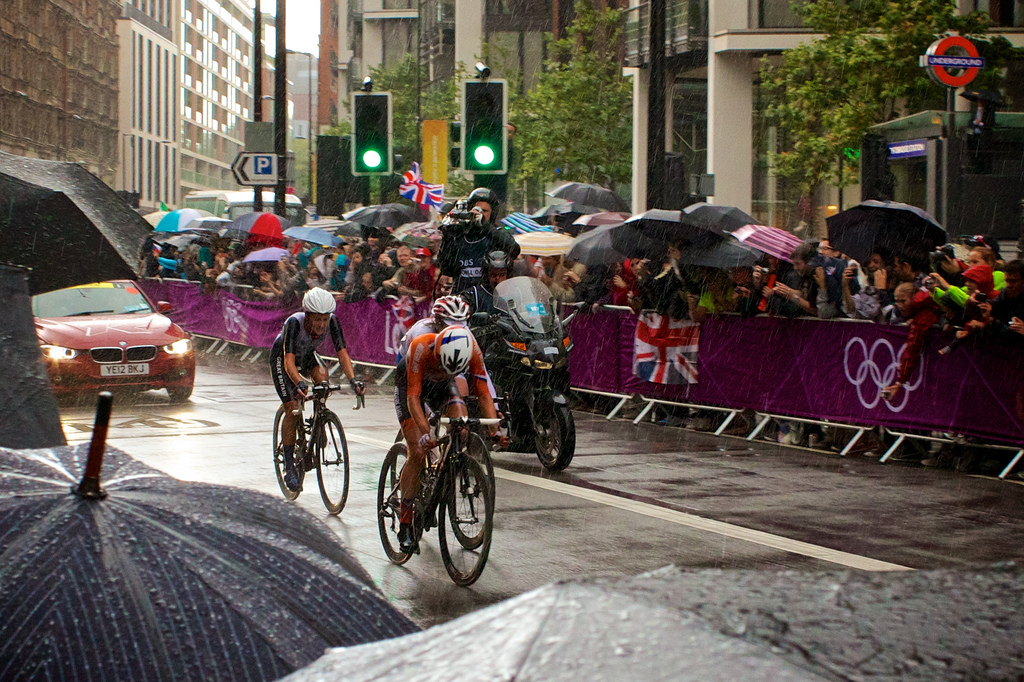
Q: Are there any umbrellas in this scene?
A: Yes, there is an umbrella.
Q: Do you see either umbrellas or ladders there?
A: Yes, there is an umbrella.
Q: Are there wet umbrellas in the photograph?
A: Yes, there is a wet umbrella.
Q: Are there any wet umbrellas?
A: Yes, there is a wet umbrella.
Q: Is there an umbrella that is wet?
A: Yes, there is an umbrella that is wet.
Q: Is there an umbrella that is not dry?
A: Yes, there is a wet umbrella.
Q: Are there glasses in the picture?
A: No, there are no glasses.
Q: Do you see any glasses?
A: No, there are no glasses.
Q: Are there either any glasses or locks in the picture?
A: No, there are no glasses or locks.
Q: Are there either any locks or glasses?
A: No, there are no glasses or locks.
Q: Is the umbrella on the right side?
A: No, the umbrella is on the left of the image.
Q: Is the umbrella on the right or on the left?
A: The umbrella is on the left of the image.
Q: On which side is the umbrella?
A: The umbrella is on the left of the image.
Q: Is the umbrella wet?
A: Yes, the umbrella is wet.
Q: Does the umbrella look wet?
A: Yes, the umbrella is wet.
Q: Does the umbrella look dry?
A: No, the umbrella is wet.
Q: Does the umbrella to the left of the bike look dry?
A: No, the umbrella is wet.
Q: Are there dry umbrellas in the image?
A: No, there is an umbrella but it is wet.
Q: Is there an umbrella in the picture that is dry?
A: No, there is an umbrella but it is wet.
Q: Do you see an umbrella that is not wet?
A: No, there is an umbrella but it is wet.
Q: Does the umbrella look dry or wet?
A: The umbrella is wet.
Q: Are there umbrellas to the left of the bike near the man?
A: Yes, there is an umbrella to the left of the bike.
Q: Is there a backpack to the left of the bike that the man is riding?
A: No, there is an umbrella to the left of the bike.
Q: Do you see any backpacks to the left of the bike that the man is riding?
A: No, there is an umbrella to the left of the bike.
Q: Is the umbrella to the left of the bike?
A: Yes, the umbrella is to the left of the bike.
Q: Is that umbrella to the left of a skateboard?
A: No, the umbrella is to the left of the bike.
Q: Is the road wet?
A: Yes, the road is wet.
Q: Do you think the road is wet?
A: Yes, the road is wet.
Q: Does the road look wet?
A: Yes, the road is wet.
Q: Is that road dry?
A: No, the road is wet.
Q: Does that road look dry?
A: No, the road is wet.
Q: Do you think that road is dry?
A: No, the road is wet.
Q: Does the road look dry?
A: No, the road is wet.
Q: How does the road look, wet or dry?
A: The road is wet.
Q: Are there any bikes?
A: Yes, there is a bike.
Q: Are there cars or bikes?
A: Yes, there is a bike.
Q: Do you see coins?
A: No, there are no coins.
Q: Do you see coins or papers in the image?
A: No, there are no coins or papers.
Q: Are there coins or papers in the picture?
A: No, there are no coins or papers.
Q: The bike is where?
A: The bike is on the road.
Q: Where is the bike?
A: The bike is on the road.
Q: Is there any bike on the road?
A: Yes, there is a bike on the road.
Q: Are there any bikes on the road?
A: Yes, there is a bike on the road.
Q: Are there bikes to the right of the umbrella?
A: Yes, there is a bike to the right of the umbrella.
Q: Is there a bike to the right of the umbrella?
A: Yes, there is a bike to the right of the umbrella.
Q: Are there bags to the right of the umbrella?
A: No, there is a bike to the right of the umbrella.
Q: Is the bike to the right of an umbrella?
A: Yes, the bike is to the right of an umbrella.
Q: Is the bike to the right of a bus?
A: No, the bike is to the right of an umbrella.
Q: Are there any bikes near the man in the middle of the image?
A: Yes, there is a bike near the man.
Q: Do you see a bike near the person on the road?
A: Yes, there is a bike near the man.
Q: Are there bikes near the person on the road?
A: Yes, there is a bike near the man.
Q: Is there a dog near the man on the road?
A: No, there is a bike near the man.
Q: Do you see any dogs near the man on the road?
A: No, there is a bike near the man.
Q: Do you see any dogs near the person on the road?
A: No, there is a bike near the man.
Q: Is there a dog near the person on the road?
A: No, there is a bike near the man.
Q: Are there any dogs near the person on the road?
A: No, there is a bike near the man.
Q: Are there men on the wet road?
A: Yes, there is a man on the road.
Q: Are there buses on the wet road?
A: No, there is a man on the road.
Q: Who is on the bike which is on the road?
A: The man is on the bike.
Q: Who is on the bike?
A: The man is on the bike.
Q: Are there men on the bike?
A: Yes, there is a man on the bike.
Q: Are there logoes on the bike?
A: No, there is a man on the bike.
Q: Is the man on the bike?
A: Yes, the man is on the bike.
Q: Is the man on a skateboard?
A: No, the man is on the bike.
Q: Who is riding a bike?
A: The man is riding a bike.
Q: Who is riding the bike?
A: The man is riding a bike.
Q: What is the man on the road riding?
A: The man is riding a bike.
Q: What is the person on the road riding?
A: The man is riding a bike.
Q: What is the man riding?
A: The man is riding a bike.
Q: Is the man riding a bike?
A: Yes, the man is riding a bike.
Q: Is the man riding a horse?
A: No, the man is riding a bike.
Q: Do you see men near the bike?
A: Yes, there is a man near the bike.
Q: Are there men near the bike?
A: Yes, there is a man near the bike.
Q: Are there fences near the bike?
A: No, there is a man near the bike.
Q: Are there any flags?
A: Yes, there is a flag.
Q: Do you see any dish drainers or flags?
A: Yes, there is a flag.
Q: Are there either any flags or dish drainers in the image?
A: Yes, there is a flag.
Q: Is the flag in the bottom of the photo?
A: No, the flag is in the top of the image.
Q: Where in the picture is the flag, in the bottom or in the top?
A: The flag is in the top of the image.